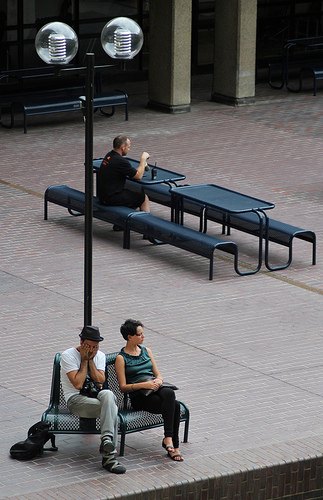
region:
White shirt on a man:
[58, 323, 135, 457]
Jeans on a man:
[66, 381, 138, 468]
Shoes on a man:
[93, 427, 127, 470]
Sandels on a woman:
[155, 432, 192, 464]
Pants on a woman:
[127, 373, 198, 445]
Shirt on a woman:
[108, 349, 169, 395]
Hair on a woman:
[115, 314, 149, 360]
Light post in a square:
[36, 24, 160, 311]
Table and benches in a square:
[54, 130, 269, 281]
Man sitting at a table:
[92, 131, 153, 221]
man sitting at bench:
[73, 122, 176, 226]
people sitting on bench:
[21, 295, 200, 472]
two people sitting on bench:
[34, 307, 195, 476]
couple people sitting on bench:
[39, 310, 197, 465]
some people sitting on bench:
[34, 299, 192, 470]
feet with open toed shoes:
[149, 427, 179, 462]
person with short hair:
[104, 308, 150, 352]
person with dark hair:
[114, 312, 147, 354]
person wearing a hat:
[70, 315, 102, 360]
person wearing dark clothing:
[94, 124, 150, 212]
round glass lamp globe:
[35, 18, 78, 68]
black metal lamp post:
[36, 53, 132, 322]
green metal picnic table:
[128, 187, 315, 274]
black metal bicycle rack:
[265, 32, 321, 97]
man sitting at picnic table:
[100, 134, 150, 214]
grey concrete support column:
[151, 0, 192, 113]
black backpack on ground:
[10, 421, 56, 457]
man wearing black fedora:
[55, 324, 125, 479]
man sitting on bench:
[59, 324, 124, 475]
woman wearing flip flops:
[118, 317, 184, 466]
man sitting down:
[96, 132, 171, 233]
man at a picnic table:
[95, 127, 160, 244]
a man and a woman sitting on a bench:
[53, 319, 199, 475]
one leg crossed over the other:
[154, 387, 191, 460]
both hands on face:
[78, 339, 101, 363]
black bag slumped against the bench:
[7, 410, 64, 466]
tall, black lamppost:
[30, 18, 151, 344]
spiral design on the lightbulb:
[113, 27, 133, 56]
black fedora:
[74, 321, 106, 342]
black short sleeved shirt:
[95, 147, 141, 205]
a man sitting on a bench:
[54, 322, 125, 471]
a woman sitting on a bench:
[115, 316, 182, 462]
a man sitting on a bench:
[97, 132, 154, 215]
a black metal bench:
[34, 350, 191, 447]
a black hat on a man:
[76, 324, 101, 341]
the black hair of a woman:
[119, 318, 141, 335]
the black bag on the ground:
[5, 433, 45, 462]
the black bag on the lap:
[132, 371, 177, 394]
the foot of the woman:
[161, 435, 174, 452]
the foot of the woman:
[169, 446, 181, 459]